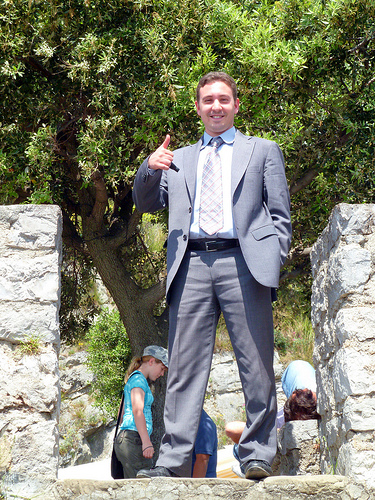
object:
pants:
[152, 237, 280, 472]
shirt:
[130, 128, 294, 290]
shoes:
[133, 457, 271, 480]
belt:
[186, 237, 240, 253]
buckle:
[204, 239, 216, 251]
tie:
[197, 137, 223, 235]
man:
[131, 70, 293, 477]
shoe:
[237, 457, 277, 477]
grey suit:
[131, 133, 294, 478]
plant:
[16, 333, 47, 358]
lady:
[279, 358, 324, 434]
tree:
[0, 1, 375, 467]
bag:
[111, 380, 134, 477]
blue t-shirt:
[192, 410, 219, 476]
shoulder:
[127, 373, 147, 386]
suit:
[126, 126, 297, 474]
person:
[114, 343, 167, 486]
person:
[192, 408, 218, 477]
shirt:
[190, 409, 216, 478]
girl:
[113, 343, 167, 478]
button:
[187, 204, 192, 214]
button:
[180, 233, 187, 241]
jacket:
[131, 127, 293, 304]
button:
[140, 171, 149, 182]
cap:
[141, 343, 171, 366]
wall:
[0, 203, 63, 498]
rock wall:
[0, 198, 375, 499]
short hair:
[194, 69, 240, 100]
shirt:
[117, 367, 155, 435]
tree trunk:
[62, 185, 167, 467]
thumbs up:
[142, 135, 178, 177]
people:
[112, 68, 322, 477]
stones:
[9, 256, 52, 300]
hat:
[138, 345, 170, 372]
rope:
[24, 23, 83, 183]